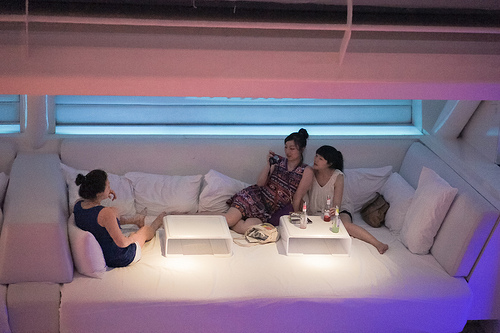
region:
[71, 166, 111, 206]
Black hair is in a bun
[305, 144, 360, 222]
Woman wearing a white dress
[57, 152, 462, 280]
White pillows on a large couch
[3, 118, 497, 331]
Three women sitting on a couch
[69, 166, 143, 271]
A lady wearing a blue dress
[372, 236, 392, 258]
A foot is bare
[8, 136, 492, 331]
front of white couch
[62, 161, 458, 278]
white pillows on couch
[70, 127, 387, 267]
three women sitting on couch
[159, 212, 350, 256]
two square white trays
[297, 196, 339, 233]
bottles on top of tray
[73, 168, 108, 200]
hair pulled back in bun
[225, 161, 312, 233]
dress with no sleeves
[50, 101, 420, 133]
light reflection on window sill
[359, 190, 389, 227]
purse in corner of couch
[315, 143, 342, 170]
black hair on woman's head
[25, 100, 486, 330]
three woman on a large sofa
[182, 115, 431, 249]
2 women sitting next to each other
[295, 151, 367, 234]
woman with white shirt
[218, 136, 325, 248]
multiprint dress on woman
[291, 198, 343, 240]
group of three bottles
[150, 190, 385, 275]
2 trays on the sofa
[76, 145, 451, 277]
pillows on the sofa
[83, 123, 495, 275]
the pillows are white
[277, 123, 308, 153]
woman has a ponytail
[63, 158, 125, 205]
woman has dark hair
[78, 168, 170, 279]
woman sitting on couch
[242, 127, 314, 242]
woman sitting on couch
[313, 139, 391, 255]
woman sitting on couch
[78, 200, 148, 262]
the shirt is blue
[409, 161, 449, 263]
the pillow is white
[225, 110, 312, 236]
the woman holds a camera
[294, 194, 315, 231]
the bottle is clear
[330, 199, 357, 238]
the bottle is clear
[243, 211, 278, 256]
the bag is white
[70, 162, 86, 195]
a bun on girl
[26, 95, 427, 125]
a long window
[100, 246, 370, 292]
light shinning on sheet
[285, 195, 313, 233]
a bottle on table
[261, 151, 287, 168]
a silver cramera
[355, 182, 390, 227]
a tan purse on couch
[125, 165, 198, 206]
a white pillow on couch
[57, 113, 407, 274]
three girls sitting on a couch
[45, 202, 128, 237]
a sleeveless dress on girl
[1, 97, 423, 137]
windows behind furniture on wall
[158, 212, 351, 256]
small white trays by people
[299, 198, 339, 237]
three glass bottle on tray